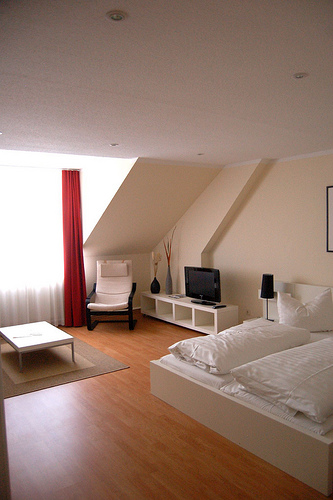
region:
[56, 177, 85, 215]
red curtains in window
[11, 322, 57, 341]
top of white table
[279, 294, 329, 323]
white pillow on bed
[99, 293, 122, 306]
padding of white chair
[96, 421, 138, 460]
brown hard wood floors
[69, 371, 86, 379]
brown outer design of carpet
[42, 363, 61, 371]
beige inner design of carpet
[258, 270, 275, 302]
black lamp shade on lamp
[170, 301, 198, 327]
cubby of white stand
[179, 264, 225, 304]
flat screen tv on stand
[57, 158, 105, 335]
red curtain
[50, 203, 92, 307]
red curtain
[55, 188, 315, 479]
photograph of bedroom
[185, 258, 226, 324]
black flat screen TV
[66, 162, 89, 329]
red curtains on side of window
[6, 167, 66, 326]
white sheer curtains covering window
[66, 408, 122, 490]
light brown wooden floor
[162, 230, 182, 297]
grey vase with tall plant in it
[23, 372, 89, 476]
light reflecting on floor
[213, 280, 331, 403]
bed with white linens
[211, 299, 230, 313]
black remote on shelf next to TV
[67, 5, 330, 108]
recessed lighting in ceiling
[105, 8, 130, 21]
Recessed light in ceiling.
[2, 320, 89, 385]
White coffee table on rug.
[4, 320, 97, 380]
Coffee table on brown and tan rug.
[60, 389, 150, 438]
Brown hardwood flooring.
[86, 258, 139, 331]
Black and white chair.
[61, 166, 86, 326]
Red curtains over window.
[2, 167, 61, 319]
White curtains over window.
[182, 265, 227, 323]
Television on white stand.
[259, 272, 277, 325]
Black lamp on nightstand.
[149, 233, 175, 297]
Black and grey vases on stand.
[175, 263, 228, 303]
a flat screen tv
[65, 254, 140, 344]
a white chair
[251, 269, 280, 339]
a small black lamp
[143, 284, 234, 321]
a white table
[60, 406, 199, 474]
hard wood flooring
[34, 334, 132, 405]
a rug on the floor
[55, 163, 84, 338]
a long red curtain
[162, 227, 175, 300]
a bottle with tall fake flowers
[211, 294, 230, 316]
a tv remote controller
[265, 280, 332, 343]
a pillow on a bed